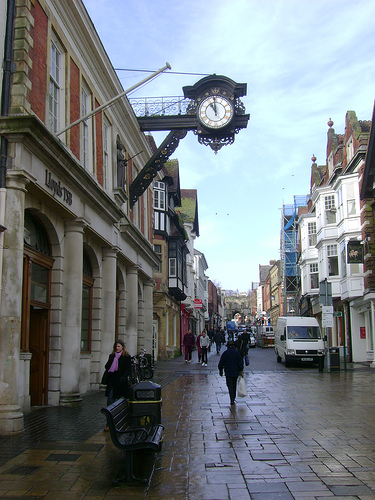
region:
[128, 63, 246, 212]
clock attached to building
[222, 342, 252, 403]
person walking with white bag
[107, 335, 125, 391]
girl with purple scarf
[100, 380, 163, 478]
black bench next to waste bin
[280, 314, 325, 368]
white truck parked on side of road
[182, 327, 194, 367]
person in red clothing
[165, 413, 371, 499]
pavement is made of brick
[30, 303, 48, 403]
door is made of wood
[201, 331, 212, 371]
person in white shirt and white sneaks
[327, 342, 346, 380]
waste bin on the corner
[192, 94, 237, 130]
black and white clock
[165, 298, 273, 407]
people on the sidewalk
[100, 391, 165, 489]
bench on the sidewalk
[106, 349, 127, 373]
purple scarf hanging down from the neck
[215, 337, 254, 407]
person holding a white plastic bag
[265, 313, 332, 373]
white van on the side of the road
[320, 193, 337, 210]
dark window on the building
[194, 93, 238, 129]
clock indicating it's 11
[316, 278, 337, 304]
back of a sign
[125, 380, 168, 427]
trash receptacle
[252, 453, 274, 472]
part of a floor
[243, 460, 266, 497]
part of a floor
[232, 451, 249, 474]
part of a floor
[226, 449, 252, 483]
edge of a crack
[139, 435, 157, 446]
edge of a bench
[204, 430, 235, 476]
part of a floor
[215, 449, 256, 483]
part of a crack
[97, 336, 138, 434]
woman walking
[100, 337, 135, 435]
woman wearing purple scarf walking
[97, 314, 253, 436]
people walking on road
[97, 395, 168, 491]
a bench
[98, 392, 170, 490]
an empty bench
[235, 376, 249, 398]
a plastic bag person is carrying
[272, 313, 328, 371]
white van on road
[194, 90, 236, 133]
clock on side of building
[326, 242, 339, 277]
a window of the building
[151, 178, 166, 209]
a window of the building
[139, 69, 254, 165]
clock suspended from the side of a building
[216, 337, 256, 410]
man walking on the street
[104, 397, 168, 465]
bench on the street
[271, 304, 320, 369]
van parked on the street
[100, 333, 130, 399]
woman walking on the sidewalk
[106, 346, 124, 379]
scarf on the woman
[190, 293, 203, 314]
red sign on a building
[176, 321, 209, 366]
people on the street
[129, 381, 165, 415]
garbage can next to a bench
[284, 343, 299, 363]
headlight on a van